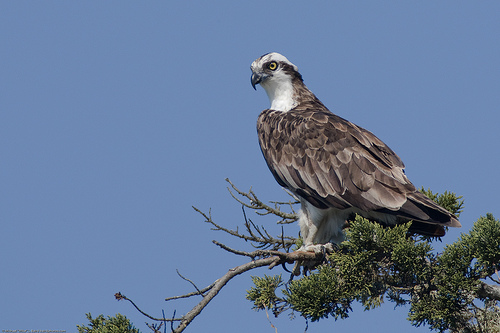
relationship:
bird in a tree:
[248, 50, 462, 255] [71, 162, 486, 327]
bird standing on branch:
[248, 50, 461, 246] [118, 179, 498, 331]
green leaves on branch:
[280, 220, 437, 305] [161, 177, 480, 332]